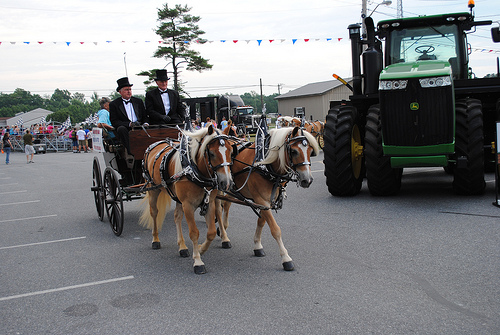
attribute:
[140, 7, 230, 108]
tree — green, tall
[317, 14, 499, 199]
tractor — green, big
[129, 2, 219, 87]
tree — large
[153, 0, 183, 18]
leaves — green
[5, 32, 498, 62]
pennant banner — white , red , Blue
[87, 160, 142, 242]
large wheels — very large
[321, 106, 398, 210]
tires — round, black, large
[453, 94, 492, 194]
tires — black, large, round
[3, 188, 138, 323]
lines — White 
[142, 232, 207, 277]
hooves — black 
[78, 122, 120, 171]
sign — white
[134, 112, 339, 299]
horses — brown 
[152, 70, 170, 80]
hat — top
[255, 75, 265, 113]
pole — wood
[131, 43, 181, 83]
hat — top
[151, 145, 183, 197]
harness — black 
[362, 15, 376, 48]
exhaust — black 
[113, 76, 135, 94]
hat — top, black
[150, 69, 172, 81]
hat — top, black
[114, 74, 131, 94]
hat — top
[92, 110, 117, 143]
shirt — light blue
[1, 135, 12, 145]
shirt — dark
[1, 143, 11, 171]
pants — blue